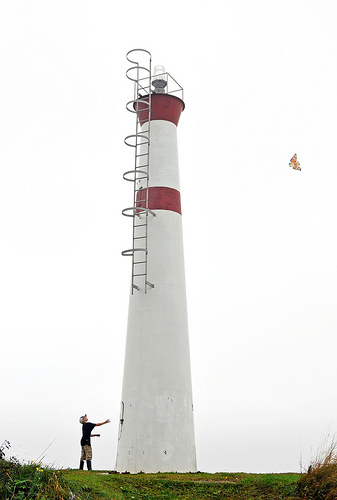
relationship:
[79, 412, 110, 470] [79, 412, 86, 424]
boy wearing hat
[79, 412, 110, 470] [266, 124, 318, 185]
boy flying a kite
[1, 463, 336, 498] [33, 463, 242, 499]
bank with flowers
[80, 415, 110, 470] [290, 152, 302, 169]
boy flying kite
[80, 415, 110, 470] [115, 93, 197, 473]
boy near lighthouse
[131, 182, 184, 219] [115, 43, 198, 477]
red stripe on lighthouse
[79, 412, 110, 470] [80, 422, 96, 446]
boy has black t-shirt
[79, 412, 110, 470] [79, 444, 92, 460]
boy has pants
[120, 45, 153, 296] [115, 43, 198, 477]
ladder on lighthouse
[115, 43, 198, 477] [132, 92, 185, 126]
lighthouse has top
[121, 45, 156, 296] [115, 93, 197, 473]
ladder on side of lighthouse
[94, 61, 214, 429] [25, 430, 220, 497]
lighthouse in field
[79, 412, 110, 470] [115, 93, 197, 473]
boy looking at lighthouse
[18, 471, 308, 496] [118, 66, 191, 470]
grass near lighthouse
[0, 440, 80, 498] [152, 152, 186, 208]
vegetation near building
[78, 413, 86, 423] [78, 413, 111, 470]
hat on boy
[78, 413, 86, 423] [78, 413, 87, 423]
hat on head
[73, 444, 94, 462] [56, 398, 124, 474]
pants on boy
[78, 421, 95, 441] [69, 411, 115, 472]
black t-shirt on boy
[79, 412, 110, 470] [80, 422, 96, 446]
boy wearing black t-shirt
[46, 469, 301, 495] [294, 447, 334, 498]
grass with bush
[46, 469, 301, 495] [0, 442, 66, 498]
grass with bush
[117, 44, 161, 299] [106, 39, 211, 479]
railing on light house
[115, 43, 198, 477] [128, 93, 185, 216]
lighthouse has stripes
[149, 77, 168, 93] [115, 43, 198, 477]
light on top of lighthouse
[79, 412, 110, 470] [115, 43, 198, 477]
boy next to lighthouse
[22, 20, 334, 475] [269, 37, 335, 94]
clouds in sky